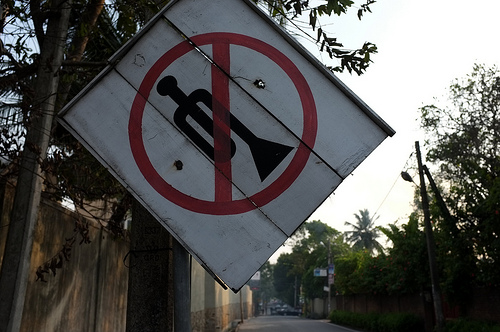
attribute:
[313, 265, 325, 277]
signs — several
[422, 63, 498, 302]
tree — green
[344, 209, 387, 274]
tree — green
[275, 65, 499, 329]
tree — green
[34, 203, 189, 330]
fence — wooden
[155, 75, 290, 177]
trombone — black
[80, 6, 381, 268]
sign — red, white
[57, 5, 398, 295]
sign — informational, white, tilted, black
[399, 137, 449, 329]
light post — tall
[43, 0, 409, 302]
sign — white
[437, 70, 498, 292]
tree — green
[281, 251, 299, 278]
tree — green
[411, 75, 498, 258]
tree — green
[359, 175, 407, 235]
wire — electric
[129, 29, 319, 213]
print — red, black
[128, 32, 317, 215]
circle — red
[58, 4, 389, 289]
planks — wood